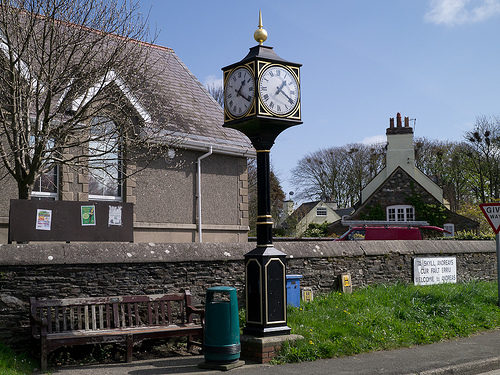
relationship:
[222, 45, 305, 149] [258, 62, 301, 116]
clock has face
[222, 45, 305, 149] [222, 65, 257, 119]
clock has face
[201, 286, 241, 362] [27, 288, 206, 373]
trashcan next to bench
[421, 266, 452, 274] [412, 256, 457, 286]
letters are written on sign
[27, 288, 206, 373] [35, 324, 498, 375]
bench on top of sidewalk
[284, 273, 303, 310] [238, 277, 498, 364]
box in grass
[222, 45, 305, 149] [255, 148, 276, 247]
clock in on pole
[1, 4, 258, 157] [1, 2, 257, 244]
roof on top of house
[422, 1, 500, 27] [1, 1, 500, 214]
cloud in sky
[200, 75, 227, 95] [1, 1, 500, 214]
cloud in sky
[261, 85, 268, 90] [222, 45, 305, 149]
roman numeral on clock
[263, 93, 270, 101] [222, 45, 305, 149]
roman numeral on clock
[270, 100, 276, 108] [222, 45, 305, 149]
roman numeral on clock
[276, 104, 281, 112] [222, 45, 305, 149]
roman numeral on clock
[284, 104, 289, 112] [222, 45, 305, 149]
roman numeral on clock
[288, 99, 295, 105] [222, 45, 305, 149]
roman numeral on clock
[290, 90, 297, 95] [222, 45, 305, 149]
roman numeral on clock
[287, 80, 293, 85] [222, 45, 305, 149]
roman numeral on clock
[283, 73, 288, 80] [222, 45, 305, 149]
roman numeral on clock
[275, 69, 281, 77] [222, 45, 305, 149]
roman numeral on clock